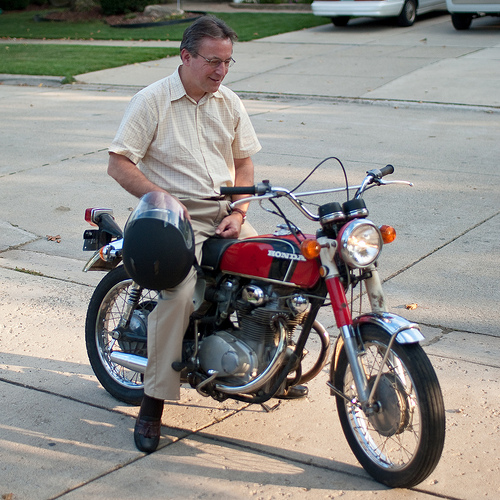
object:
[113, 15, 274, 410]
man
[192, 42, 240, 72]
glasses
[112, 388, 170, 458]
shoe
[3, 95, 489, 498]
pavement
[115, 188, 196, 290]
helmet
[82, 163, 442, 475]
motorcycle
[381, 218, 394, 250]
light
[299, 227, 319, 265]
light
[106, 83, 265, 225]
shirt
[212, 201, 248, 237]
hand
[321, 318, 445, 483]
wheel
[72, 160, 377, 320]
down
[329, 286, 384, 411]
pipes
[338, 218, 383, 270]
headlight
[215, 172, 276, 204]
handlebars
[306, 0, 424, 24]
cars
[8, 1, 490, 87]
background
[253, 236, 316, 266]
honda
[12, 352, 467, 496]
shadow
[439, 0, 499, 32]
vehicles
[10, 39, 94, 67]
lawn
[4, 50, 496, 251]
street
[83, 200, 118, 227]
tail lights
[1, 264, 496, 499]
floor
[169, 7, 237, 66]
hair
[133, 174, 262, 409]
pants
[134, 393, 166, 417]
socks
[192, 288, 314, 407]
engine